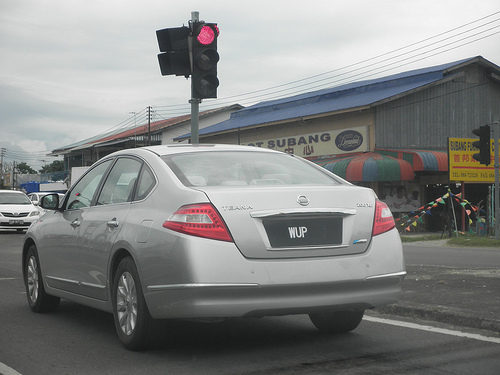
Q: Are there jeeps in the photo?
A: No, there are no jeeps.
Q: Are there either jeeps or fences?
A: No, there are no jeeps or fences.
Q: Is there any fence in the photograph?
A: No, there are no fences.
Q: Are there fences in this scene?
A: No, there are no fences.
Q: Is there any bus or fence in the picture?
A: No, there are no fences or buses.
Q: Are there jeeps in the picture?
A: No, there are no jeeps.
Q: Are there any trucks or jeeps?
A: No, there are no jeeps or trucks.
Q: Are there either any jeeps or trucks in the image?
A: No, there are no jeeps or trucks.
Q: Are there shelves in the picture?
A: No, there are no shelves.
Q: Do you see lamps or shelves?
A: No, there are no shelves or lamps.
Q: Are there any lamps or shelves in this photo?
A: No, there are no shelves or lamps.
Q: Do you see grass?
A: Yes, there is grass.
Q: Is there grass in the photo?
A: Yes, there is grass.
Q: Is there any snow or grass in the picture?
A: Yes, there is grass.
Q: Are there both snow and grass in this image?
A: No, there is grass but no snow.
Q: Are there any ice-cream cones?
A: No, there are no ice-cream cones.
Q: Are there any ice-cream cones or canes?
A: No, there are no ice-cream cones or canes.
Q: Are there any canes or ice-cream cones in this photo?
A: No, there are no ice-cream cones or canes.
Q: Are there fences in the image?
A: No, there are no fences.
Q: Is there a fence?
A: No, there are no fences.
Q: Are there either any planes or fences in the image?
A: No, there are no fences or planes.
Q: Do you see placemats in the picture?
A: No, there are no placemats.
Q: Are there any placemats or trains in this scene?
A: No, there are no placemats or trains.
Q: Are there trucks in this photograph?
A: No, there are no trucks.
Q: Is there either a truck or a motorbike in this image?
A: No, there are no trucks or motorcycles.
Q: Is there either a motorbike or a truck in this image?
A: No, there are no trucks or motorcycles.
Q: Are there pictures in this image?
A: No, there are no pictures.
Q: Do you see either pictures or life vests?
A: No, there are no pictures or life vests.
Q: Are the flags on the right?
A: Yes, the flags are on the right of the image.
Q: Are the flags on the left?
A: No, the flags are on the right of the image.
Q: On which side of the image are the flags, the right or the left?
A: The flags are on the right of the image.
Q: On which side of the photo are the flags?
A: The flags are on the right of the image.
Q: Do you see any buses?
A: No, there are no buses.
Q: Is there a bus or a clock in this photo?
A: No, there are no buses or clocks.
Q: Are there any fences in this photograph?
A: No, there are no fences.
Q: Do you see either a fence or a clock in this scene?
A: No, there are no fences or clocks.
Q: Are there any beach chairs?
A: No, there are no beach chairs.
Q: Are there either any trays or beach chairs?
A: No, there are no beach chairs or trays.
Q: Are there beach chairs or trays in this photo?
A: No, there are no beach chairs or trays.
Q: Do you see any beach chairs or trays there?
A: No, there are no beach chairs or trays.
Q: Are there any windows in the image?
A: Yes, there is a window.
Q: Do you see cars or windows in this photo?
A: Yes, there is a window.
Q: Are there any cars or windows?
A: Yes, there is a window.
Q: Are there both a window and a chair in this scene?
A: No, there is a window but no chairs.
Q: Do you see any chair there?
A: No, there are no chairs.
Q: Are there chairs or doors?
A: No, there are no chairs or doors.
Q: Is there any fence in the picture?
A: No, there are no fences.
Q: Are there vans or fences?
A: No, there are no fences or vans.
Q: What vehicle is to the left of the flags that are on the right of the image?
A: The vehicle is a car.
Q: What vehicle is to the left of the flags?
A: The vehicle is a car.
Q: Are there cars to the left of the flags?
A: Yes, there is a car to the left of the flags.